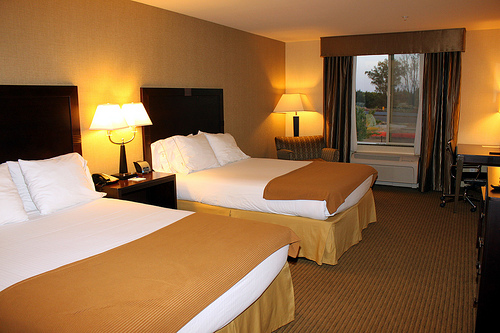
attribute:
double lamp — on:
[89, 102, 153, 180]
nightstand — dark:
[94, 169, 179, 213]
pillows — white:
[152, 130, 252, 175]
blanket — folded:
[262, 160, 378, 214]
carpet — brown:
[267, 185, 482, 332]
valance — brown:
[320, 27, 467, 58]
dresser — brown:
[473, 165, 500, 331]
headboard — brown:
[140, 86, 225, 171]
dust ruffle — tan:
[177, 187, 377, 267]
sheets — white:
[152, 157, 373, 220]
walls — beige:
[0, 0, 500, 176]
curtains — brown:
[320, 28, 467, 191]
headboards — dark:
[1, 84, 225, 163]